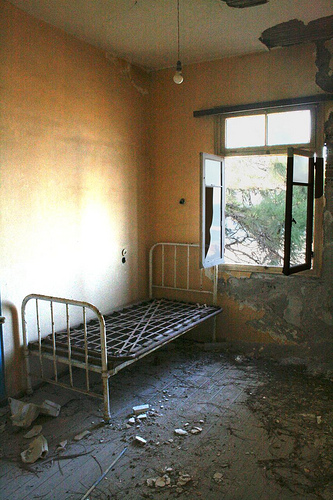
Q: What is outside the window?
A: Trees.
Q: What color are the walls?
A: Orange.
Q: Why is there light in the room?
A: Sunshine.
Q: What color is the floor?
A: Gray.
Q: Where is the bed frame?
A: Corner.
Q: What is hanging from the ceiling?
A: Light.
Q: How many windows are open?
A: One.